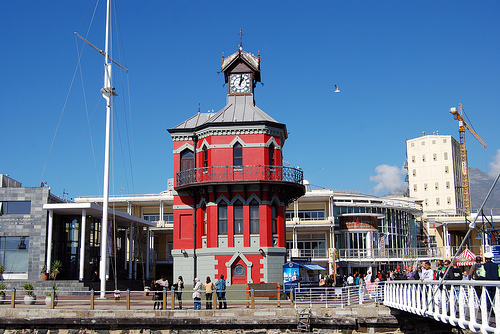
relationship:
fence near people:
[385, 281, 500, 333] [389, 259, 498, 278]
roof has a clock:
[223, 51, 261, 106] [229, 74, 252, 94]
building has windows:
[165, 52, 305, 296] [232, 139, 245, 168]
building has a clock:
[165, 52, 305, 296] [229, 74, 252, 94]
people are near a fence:
[389, 259, 498, 278] [385, 281, 498, 333]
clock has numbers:
[229, 74, 252, 94] [231, 74, 250, 95]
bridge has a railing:
[383, 280, 500, 333] [380, 279, 498, 287]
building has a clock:
[165, 26, 306, 291] [229, 74, 252, 94]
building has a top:
[165, 26, 306, 291] [218, 52, 262, 105]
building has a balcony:
[165, 26, 306, 291] [174, 166, 304, 202]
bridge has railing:
[383, 280, 500, 333] [380, 279, 498, 287]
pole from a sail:
[75, 0, 131, 298] [76, 0, 132, 296]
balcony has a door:
[174, 166, 304, 202] [230, 258, 249, 283]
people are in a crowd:
[389, 259, 498, 278] [386, 257, 498, 280]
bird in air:
[333, 84, 341, 93] [1, 0, 500, 213]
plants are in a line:
[24, 286, 36, 305] [3, 284, 63, 308]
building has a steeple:
[165, 26, 306, 291] [220, 29, 260, 105]